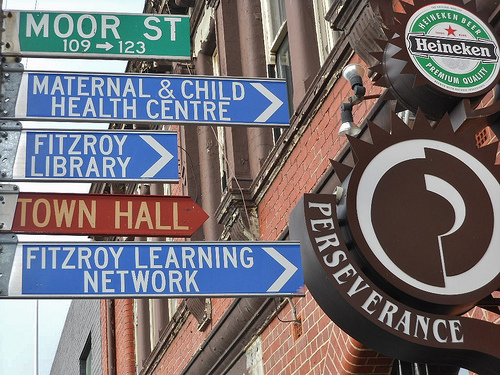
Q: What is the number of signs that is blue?
A: Three.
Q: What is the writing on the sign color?
A: White.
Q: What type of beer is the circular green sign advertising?
A: Heineken.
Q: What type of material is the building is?
A: Brick.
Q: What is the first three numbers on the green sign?
A: 109.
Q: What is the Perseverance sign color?
A: Brown and white.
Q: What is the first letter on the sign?
A: M.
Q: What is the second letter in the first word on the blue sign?
A: I.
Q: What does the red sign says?
A: Town Hall.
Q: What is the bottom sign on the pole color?
A: Blue.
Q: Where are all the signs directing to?
A: The right.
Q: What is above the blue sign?
A: A green and white street sign.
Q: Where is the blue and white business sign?
A: On the pole.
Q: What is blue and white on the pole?
A: Business sign.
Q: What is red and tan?
A: Government sign.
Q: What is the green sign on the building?
A: An advertisement for beer.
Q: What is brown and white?
A: A fancy sign.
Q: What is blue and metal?
A: Street sign.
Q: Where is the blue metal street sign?
A: On the pole.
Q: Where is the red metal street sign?
A: On pole.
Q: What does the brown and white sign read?
A: It reads 'PERSEVERANCE'.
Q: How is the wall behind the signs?
A: Brick red wall.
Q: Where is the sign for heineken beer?
A: On the side of a building.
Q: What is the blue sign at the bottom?
A: FITZROY LEARNING NETWORK.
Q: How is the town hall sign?
A: Red and white.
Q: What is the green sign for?
A: For Moor street.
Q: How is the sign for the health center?
A: Blue sign with white letters.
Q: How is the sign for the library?
A: Blue.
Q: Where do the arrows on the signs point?
A: To the right.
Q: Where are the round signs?
A: On building.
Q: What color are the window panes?
A: Brown.